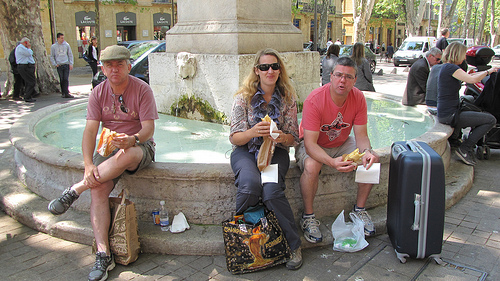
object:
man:
[47, 44, 159, 280]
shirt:
[79, 73, 159, 145]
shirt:
[297, 81, 368, 151]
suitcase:
[386, 136, 448, 269]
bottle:
[157, 197, 172, 234]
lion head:
[175, 51, 198, 80]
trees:
[371, 0, 409, 20]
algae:
[169, 93, 230, 125]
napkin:
[354, 160, 383, 184]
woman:
[424, 39, 500, 164]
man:
[49, 31, 78, 99]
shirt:
[49, 41, 74, 69]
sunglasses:
[256, 62, 281, 72]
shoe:
[46, 184, 84, 216]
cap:
[97, 44, 134, 63]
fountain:
[1, 1, 479, 258]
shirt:
[425, 60, 465, 118]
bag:
[91, 187, 144, 267]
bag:
[330, 207, 371, 253]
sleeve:
[84, 85, 104, 122]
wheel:
[431, 256, 446, 265]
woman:
[227, 47, 303, 271]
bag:
[222, 203, 294, 277]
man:
[294, 53, 380, 243]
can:
[151, 206, 161, 229]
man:
[14, 37, 39, 104]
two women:
[321, 40, 377, 93]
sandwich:
[342, 148, 371, 168]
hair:
[440, 40, 468, 65]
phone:
[23, 40, 30, 47]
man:
[400, 45, 445, 108]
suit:
[401, 57, 433, 107]